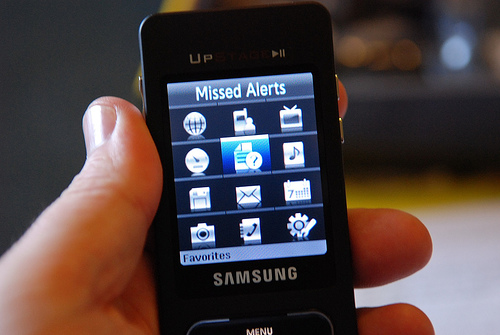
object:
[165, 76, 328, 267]
phone screen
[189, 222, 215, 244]
camera icon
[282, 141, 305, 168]
music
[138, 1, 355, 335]
cellphone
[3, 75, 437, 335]
hand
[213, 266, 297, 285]
brand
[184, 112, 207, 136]
apps